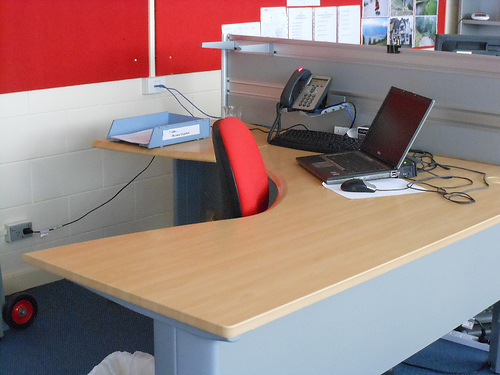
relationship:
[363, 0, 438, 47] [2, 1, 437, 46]
pictures hung on wall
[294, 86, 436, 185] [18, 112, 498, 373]
computer on desk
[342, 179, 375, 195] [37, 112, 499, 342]
mouse on desk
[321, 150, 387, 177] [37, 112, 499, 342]
keyboard on desk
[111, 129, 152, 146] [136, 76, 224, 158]
paper in inbox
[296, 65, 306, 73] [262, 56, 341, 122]
light on phone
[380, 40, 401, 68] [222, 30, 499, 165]
clamp attached to divider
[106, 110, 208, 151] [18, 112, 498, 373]
tray on desk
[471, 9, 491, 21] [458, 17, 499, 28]
clock on shelf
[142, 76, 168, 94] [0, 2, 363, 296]
outlet on wall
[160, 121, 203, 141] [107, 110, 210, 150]
sticker on shelf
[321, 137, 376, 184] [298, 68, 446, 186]
keyboard on laptop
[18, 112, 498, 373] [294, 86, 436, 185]
desk with computer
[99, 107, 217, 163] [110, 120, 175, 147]
holder with paper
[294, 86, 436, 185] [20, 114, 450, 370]
computer on desk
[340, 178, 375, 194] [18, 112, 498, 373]
mouse on a desk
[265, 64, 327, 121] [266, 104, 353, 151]
phone on a stand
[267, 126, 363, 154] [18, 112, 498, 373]
keyboard on desk